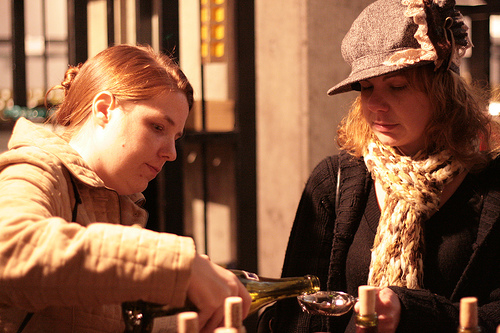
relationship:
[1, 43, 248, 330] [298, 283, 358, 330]
woman pouring into glass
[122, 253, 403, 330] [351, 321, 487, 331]
corks in tops of bottles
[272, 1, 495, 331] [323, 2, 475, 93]
woman wearing brown hat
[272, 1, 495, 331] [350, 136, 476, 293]
woman wearing scarf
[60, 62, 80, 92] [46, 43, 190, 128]
bun in hair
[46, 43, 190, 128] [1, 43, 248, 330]
hair of woman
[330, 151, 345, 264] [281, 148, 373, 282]
strap on shoulder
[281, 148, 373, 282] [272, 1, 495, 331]
shoulder of woman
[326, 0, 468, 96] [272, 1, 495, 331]
brown hat of woman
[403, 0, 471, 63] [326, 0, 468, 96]
decoration on brown hat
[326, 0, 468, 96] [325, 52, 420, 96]
brown hat with brim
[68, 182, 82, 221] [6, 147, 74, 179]
strap around shoulder